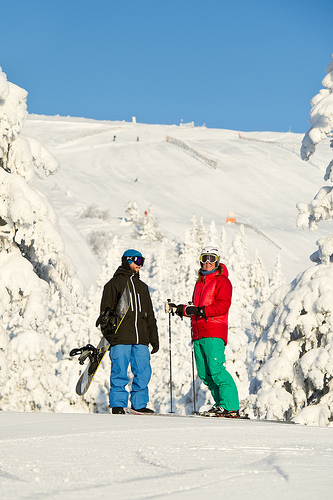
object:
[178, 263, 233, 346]
jacket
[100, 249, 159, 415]
man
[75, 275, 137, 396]
snowboard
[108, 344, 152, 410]
pants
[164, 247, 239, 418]
woman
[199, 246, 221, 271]
helmet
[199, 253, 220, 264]
goggles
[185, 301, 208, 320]
gloves